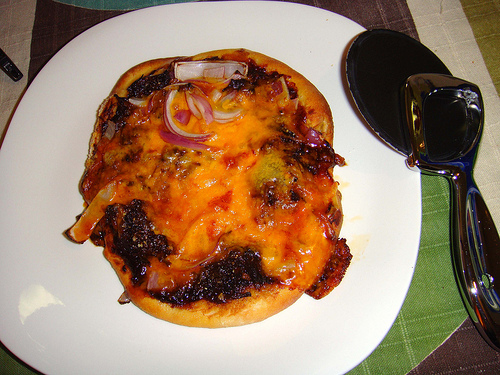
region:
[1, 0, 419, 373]
Baked pizza on white plate.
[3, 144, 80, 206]
The plate is white.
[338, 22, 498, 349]
The spoon is next to the plate.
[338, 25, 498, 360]
The spoon is silver in color.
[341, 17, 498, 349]
The spoon is made of metal.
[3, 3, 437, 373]
The plate is round.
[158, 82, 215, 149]
The onion is red.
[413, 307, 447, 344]
The placemat is green.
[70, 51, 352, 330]
The food is on the plate.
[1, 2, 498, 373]
The plate is on the table.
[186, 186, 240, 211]
The cheese is orange.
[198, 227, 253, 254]
sauce on a pizza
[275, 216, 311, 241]
sauce on a pizza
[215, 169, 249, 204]
sauce on a pizza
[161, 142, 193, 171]
sauce on a pizza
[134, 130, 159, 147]
sauce on a pizza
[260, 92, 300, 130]
sauce on a pizza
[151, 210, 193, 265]
sauce on a pizza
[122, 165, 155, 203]
sauce on a pizza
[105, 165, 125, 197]
sauce on a pizza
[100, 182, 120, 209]
sauce on a pizza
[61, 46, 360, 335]
food on white plate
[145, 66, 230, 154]
onions on top of food on plate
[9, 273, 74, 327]
white light reflecting on surface of plate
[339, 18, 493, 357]
metal spoon on side of white plate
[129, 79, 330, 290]
cheese on top of food on plate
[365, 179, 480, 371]
green and white plaid pattern on placemat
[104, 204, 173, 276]
dark burn marks on cheese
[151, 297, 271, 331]
crust of bread product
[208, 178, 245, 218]
red food mixed in with cheese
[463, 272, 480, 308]
light reflecting on metal utensil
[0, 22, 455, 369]
this is a plate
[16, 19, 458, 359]
the plate is white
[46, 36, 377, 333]
this is a pizza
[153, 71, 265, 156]
onions on the pizza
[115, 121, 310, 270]
cheese on the pizza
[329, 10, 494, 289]
this is a pizza cutter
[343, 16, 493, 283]
the pizza cutter is silver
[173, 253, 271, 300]
black spot on pizza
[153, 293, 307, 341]
brown crust on pizza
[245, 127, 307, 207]
green spot on pizza